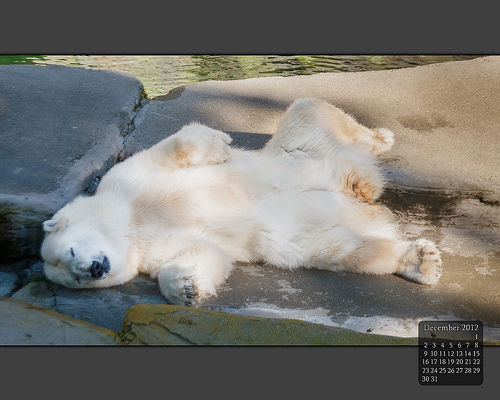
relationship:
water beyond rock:
[0, 55, 483, 102] [130, 65, 495, 211]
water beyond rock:
[0, 55, 483, 102] [0, 60, 146, 253]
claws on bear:
[179, 277, 201, 311] [37, 93, 446, 312]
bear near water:
[37, 93, 446, 312] [3, 53, 498, 83]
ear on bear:
[31, 204, 81, 237] [40, 96, 442, 308]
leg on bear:
[261, 82, 396, 179] [40, 96, 442, 308]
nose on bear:
[92, 256, 114, 283] [37, 93, 446, 312]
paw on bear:
[173, 121, 235, 167] [37, 93, 446, 312]